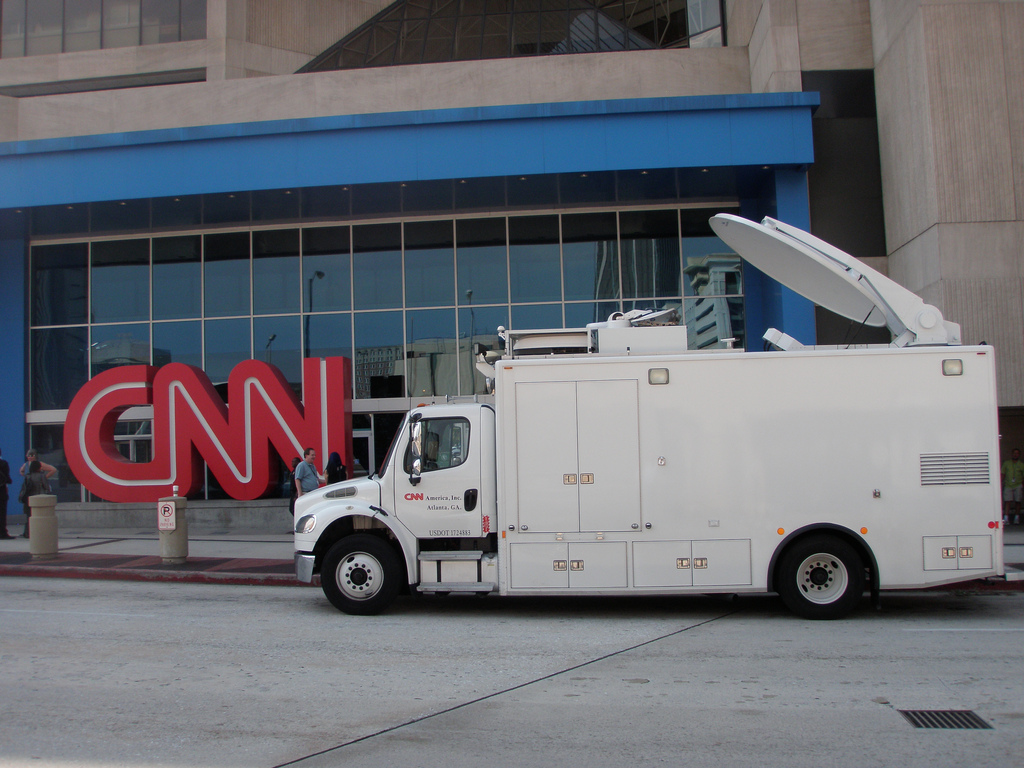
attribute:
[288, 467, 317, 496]
shirt — blue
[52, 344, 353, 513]
sign — red, the red, cable, t.v.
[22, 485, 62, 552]
post — stone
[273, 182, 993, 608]
truck — white, news, CNN, SATELLITE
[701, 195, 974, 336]
dish — white, satellite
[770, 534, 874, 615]
tire — rear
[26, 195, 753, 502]
windows — glass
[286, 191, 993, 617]
van — news, WHITE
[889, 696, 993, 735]
grate — GROUND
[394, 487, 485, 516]
sticker — CABLE, NEWS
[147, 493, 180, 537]
sign — PARKING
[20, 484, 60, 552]
post — SMALL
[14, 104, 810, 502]
area — BLUE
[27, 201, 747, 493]
panes — GLASS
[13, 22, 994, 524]
building — CABLE, NEWS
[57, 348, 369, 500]
sign — LARGER THAN LIFE, CNN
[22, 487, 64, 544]
post — CONCRETE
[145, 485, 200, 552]
post — CONCRETE